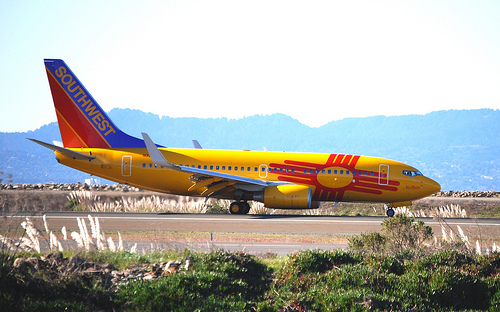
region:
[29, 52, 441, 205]
a yellow red and blue large plane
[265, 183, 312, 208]
the yellow engine of a plane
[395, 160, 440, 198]
the yellow nose of a plane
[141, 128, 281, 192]
the silver wing of a plane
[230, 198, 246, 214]
the black and yellow wheel of a plane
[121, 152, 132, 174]
the door of a plane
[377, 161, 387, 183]
the door of a plane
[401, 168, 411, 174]
the window of a plane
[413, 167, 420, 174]
the window of a plane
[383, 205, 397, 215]
the smaller wheel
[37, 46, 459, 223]
a large yellow plane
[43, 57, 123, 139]
southwest symbol on the fin of the aircraft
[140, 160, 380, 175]
passenger windows on the plane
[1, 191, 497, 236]
the landing strip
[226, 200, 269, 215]
the landing wheels on the aircraft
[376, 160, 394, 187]
an exit door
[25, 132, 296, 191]
wings on the plane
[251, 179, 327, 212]
the engines that get the plane moving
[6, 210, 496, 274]
plants that line the landing area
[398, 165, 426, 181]
front windows for the pilot to see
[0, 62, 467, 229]
a yellow, red and blue plane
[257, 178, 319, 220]
engine on a airplane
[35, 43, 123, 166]
tail wing on a air plane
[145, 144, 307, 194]
right wing on a airplane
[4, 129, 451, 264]
a plane on a runway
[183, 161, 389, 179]
a row of windows on a airplane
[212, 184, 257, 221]
wheels on a airplane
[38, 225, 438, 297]
grass and weeds next the runway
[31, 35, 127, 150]
yellow letters painted on airplane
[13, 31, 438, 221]
a airplane parked on a runway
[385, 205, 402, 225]
Front wheel of a plane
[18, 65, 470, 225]
Plane on a runway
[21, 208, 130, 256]
White flowers on plants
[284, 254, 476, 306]
Shrubs in front of a runway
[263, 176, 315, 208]
Yellow engine on the side of a plane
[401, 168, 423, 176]
Windshield in the front of a plane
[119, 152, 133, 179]
Door on the back of a plane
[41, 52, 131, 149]
Orange red blue tail fin of a plane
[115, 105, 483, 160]
Mountains behind a plane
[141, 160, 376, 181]
Passenger windows on a plane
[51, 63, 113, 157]
airplane has name on tail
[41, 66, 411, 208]
airplane is red yellow and blue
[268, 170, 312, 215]
airplane with yellow engine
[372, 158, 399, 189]
door on airplane trimmed in white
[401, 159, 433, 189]
front window of colorful airplane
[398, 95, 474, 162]
large hills in the distance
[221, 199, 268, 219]
landing gear is yellow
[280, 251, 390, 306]
green leafy bushes near runway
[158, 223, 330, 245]
runway airplane sits on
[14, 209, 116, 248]
fluffy white plant by runway